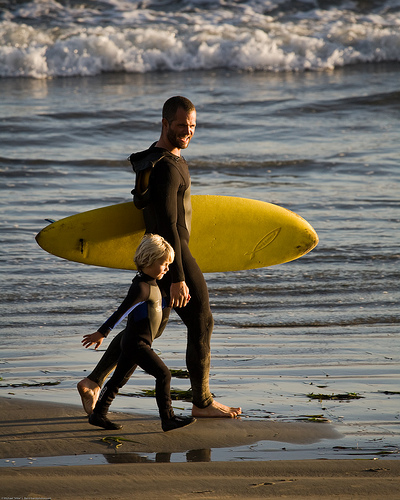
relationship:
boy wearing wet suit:
[80, 229, 198, 434] [96, 276, 182, 417]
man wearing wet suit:
[77, 95, 244, 419] [89, 141, 217, 409]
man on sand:
[77, 95, 244, 419] [0, 391, 399, 498]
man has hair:
[77, 95, 244, 419] [161, 95, 196, 120]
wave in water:
[0, 10, 400, 68] [3, 4, 393, 285]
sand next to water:
[17, 324, 399, 494] [3, 4, 393, 285]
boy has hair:
[80, 229, 198, 434] [133, 229, 178, 265]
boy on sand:
[80, 229, 198, 434] [17, 324, 399, 494]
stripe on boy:
[96, 322, 119, 332] [80, 229, 198, 434]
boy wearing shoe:
[80, 229, 198, 434] [165, 411, 199, 431]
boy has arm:
[80, 229, 198, 434] [85, 284, 147, 352]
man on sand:
[77, 95, 244, 419] [17, 324, 399, 494]